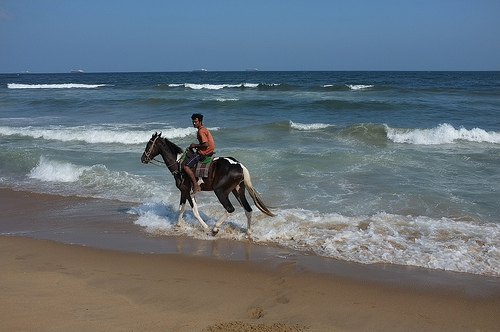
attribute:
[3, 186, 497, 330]
sand — wet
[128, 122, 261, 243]
horse — saddled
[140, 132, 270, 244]
horse — black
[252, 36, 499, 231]
waves — small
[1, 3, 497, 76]
sky — clear, blue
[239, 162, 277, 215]
tail — long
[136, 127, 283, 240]
horse — black, white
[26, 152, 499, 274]
water — white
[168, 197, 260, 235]
legs — white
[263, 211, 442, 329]
beach — sandy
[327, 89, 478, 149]
water — blue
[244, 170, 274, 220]
tail — white